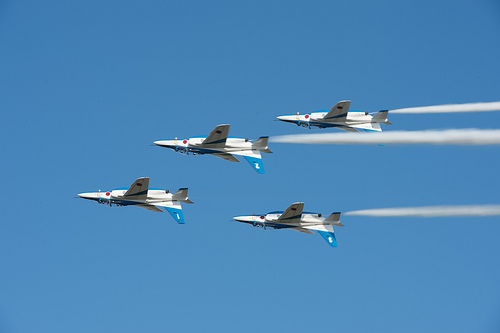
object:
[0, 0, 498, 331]
sky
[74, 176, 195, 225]
airplane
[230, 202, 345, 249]
airplane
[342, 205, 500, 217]
smoke trail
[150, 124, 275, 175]
airplane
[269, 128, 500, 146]
smoke trail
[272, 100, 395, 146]
airplane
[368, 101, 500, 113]
smoke trail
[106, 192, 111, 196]
dot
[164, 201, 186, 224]
tail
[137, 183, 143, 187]
circle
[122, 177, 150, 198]
wing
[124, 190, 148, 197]
stripe